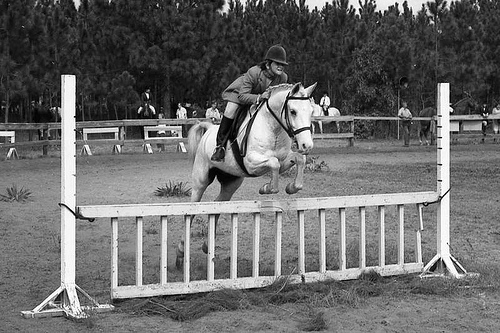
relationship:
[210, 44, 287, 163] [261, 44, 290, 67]
girl wearing helmet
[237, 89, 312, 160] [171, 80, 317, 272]
reins on horse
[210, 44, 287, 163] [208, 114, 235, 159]
girl wearing boots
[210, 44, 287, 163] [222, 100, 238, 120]
girl wearing pants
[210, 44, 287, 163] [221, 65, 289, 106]
girl wearing coat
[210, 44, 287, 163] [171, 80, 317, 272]
girl riding horse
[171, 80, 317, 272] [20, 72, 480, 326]
horse jumping fence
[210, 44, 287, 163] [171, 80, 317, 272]
girl on horse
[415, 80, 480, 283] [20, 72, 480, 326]
pole supporting fence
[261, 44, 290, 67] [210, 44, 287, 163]
helmet on girl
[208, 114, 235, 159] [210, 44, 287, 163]
boots on girl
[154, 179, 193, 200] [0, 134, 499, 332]
plant on ground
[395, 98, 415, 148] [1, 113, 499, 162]
man leaning on fence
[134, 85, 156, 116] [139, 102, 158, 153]
person riding horse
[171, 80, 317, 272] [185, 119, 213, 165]
horse has tail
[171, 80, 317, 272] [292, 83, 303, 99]
horse has ear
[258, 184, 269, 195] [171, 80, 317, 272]
hoof of horse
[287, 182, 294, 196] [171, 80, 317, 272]
hoof of horse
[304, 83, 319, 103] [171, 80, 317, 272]
ear of horse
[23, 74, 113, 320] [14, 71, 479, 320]
post to gate